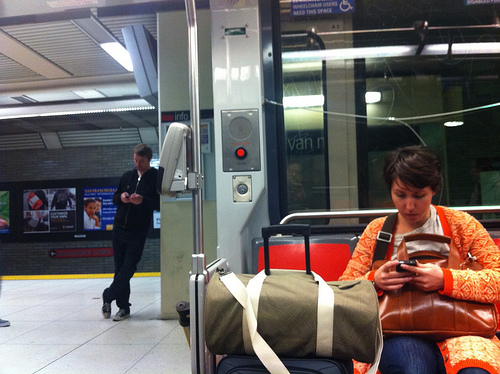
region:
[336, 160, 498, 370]
lady on cell phone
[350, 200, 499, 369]
an orange long sleeve shirt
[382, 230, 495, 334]
a large brown leather pocket book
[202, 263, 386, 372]
an olive dufflebag with white straps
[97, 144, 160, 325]
a guy leaning against a wall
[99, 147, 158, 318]
a guy on a cell phone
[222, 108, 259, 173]
a speaker with a grey cover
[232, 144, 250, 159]
a small red button with black trim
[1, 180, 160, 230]
advertisements on wall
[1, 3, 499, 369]
a station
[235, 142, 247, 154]
A red button on a door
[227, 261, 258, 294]
a green and white bag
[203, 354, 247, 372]
A blue suit case on the ground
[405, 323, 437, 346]
A woman holding her purse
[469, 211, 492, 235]
The woman is wearing a orange shirt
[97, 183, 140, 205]
A man on his phone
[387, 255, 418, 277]
A woman on her phone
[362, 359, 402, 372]
A woman wearing blue jeans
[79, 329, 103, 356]
White tile on the floor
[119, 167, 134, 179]
A man wearing a black jacket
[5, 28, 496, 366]
People are waiting at a station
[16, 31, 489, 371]
Passengers are in an airport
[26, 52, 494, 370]
Passengers are waiting for their flight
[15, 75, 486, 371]
People are going to ride a train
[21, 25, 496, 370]
People are using their cell phones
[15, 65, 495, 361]
The people are texting their friends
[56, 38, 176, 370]
A man is leaning against the wall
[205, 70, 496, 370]
A woman is seated in a chair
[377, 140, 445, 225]
A person has dark colored hair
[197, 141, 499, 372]
A person is sitting with their bags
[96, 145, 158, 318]
man wearing black sneakers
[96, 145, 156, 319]
man wearing black pants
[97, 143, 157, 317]
man wearing black sweatshirt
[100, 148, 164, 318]
man leaning against wall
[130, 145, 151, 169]
man has brown hair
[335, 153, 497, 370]
woman wearing orange sweater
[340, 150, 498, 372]
woman wearing white shirt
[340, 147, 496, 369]
woman wearing blue jeans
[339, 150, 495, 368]
woman holding leather purse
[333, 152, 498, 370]
woman has mobile phone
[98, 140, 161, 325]
Man leaning on the wall texting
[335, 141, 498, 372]
Woman sitting and looking at her phone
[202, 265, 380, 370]
Canvas bag with white stripes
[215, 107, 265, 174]
Grey communication divice on the pillar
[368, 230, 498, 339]
Brown handbag in the womans lap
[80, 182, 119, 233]
Bright blue bill board behind the man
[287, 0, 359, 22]
Blue handicap sign above the woman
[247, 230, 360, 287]
Orange and grey seat next to the woman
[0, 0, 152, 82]
Metal ceiling above the man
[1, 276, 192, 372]
Tile floor in the walkway